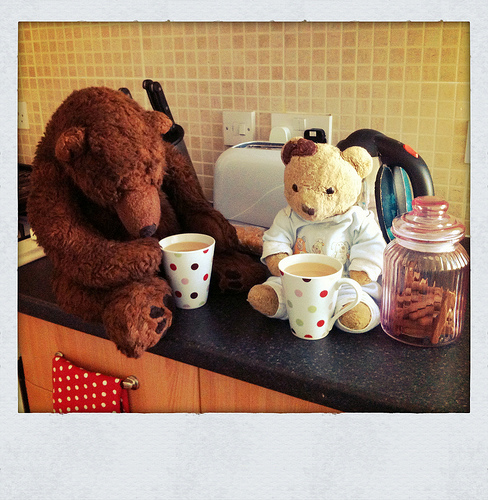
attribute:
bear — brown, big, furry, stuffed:
[19, 85, 269, 360]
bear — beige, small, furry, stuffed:
[241, 125, 390, 346]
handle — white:
[328, 277, 364, 332]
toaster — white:
[199, 132, 319, 236]